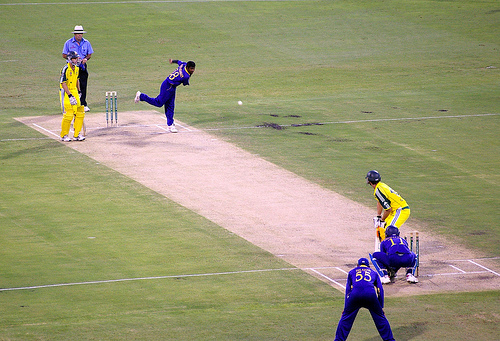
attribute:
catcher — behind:
[367, 225, 416, 282]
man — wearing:
[372, 224, 418, 283]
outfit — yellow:
[373, 182, 408, 237]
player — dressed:
[365, 167, 410, 252]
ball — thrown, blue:
[234, 97, 244, 107]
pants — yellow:
[55, 90, 90, 140]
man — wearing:
[58, 51, 88, 141]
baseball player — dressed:
[365, 168, 410, 237]